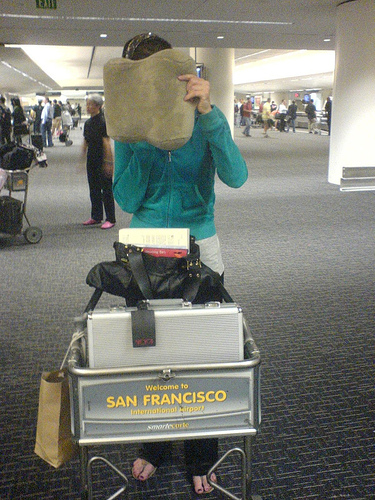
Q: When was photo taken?
A: Daytime.